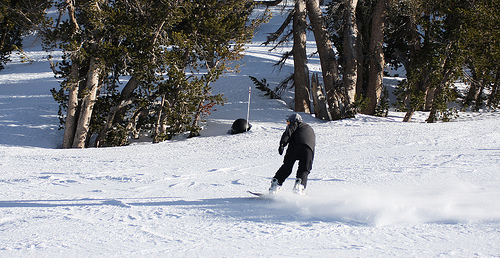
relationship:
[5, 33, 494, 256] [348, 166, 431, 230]
ground covered in snow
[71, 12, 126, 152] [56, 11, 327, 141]
evergreen trees in forest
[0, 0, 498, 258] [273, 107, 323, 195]
snow caused by snowboarder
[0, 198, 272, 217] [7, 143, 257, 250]
shadow on snow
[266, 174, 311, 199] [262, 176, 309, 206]
boots on feet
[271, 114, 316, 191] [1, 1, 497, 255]
man snowboarding in snow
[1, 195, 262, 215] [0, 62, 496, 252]
shadow on ground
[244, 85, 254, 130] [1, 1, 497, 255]
metal pole standing in snow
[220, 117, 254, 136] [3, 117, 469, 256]
object sticking out of snow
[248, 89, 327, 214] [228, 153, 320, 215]
man on snow board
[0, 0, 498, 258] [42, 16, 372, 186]
snow on hill side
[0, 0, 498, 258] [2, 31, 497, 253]
snow on hill side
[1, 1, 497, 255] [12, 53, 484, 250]
snow on hill side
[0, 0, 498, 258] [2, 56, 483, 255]
snow on hillside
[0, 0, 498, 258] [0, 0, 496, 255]
snow on ground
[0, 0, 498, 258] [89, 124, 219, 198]
snow on hill side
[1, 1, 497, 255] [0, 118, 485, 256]
snow on hillside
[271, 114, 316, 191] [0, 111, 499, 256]
man coming down slope